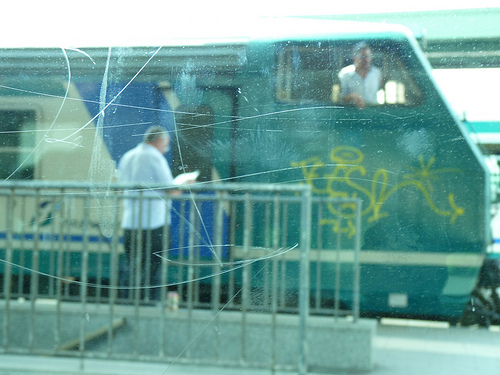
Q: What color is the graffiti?
A: Yellow.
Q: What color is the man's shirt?
A: White.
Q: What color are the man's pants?
A: Black.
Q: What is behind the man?
A: A railing.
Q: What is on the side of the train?
A: Graffiti.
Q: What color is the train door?
A: Blue and green.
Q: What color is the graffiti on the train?
A: Yellow.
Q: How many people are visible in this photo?
A: Two.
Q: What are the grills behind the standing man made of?
A: Metal.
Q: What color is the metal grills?
A: Silver.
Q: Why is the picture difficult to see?
A: Not a clear photo.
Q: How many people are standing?
A: One.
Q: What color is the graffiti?
A: Yellow.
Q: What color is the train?
A: Green.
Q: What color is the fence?
A: Gray.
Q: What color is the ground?
A: Gray.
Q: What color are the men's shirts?
A: White.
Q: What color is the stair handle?
A: Gray.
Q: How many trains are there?
A: One.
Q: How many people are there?
A: Two.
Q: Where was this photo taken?
A: Train station.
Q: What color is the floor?
A: Gray.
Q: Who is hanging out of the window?
A: Conductor.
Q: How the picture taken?
A: Through a window.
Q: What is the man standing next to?
A: A train.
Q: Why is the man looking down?
A: Looking at a paper.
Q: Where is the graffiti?
A: On the front of the train.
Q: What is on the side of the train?
A: A man.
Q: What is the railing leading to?
A: Downstairs.